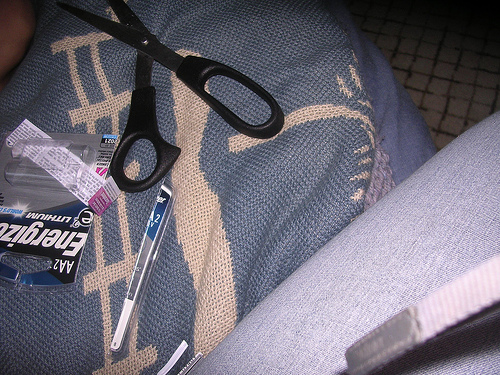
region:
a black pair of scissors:
[76, 0, 284, 193]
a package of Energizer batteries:
[0, 119, 118, 287]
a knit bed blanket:
[283, 0, 395, 193]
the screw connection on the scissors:
[137, 33, 152, 50]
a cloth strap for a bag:
[343, 255, 498, 372]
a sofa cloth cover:
[438, 145, 498, 257]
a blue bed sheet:
[375, 38, 434, 163]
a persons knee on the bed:
[1, 0, 34, 96]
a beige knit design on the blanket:
[286, 42, 376, 211]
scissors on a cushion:
[91, 25, 262, 178]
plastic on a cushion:
[6, 141, 132, 297]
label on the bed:
[14, 114, 125, 214]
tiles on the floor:
[391, 25, 490, 126]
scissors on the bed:
[4, 105, 200, 322]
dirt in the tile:
[398, 31, 496, 99]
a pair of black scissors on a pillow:
[54, 3, 292, 191]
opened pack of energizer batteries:
[1, 130, 126, 292]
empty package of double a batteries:
[4, 129, 120, 290]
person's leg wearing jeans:
[154, 100, 499, 372]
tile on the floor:
[335, 0, 495, 162]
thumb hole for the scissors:
[104, 100, 181, 192]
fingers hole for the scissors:
[176, 49, 290, 144]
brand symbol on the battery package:
[0, 222, 85, 258]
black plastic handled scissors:
[69, 6, 290, 189]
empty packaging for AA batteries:
[8, 130, 109, 298]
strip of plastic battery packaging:
[114, 177, 178, 351]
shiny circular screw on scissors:
[133, 33, 149, 49]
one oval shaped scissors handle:
[176, 47, 284, 144]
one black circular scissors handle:
[112, 127, 177, 193]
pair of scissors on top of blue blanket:
[33, 3, 316, 183]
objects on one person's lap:
[18, 9, 478, 358]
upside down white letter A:
[65, 256, 75, 280]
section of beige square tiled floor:
[401, 26, 486, 99]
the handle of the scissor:
[110, 85, 191, 195]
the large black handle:
[177, 48, 287, 143]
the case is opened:
[0, 132, 118, 292]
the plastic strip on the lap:
[107, 178, 178, 358]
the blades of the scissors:
[62, 0, 183, 87]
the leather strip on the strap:
[347, 307, 419, 374]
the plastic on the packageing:
[6, 137, 89, 191]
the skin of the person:
[0, 0, 41, 77]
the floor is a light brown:
[348, 0, 499, 153]